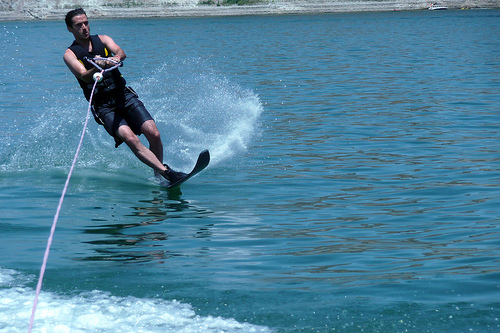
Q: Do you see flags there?
A: No, there are no flags.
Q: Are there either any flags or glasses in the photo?
A: No, there are no flags or glasses.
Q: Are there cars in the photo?
A: No, there are no cars.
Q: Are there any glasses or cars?
A: No, there are no cars or glasses.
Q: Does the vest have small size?
A: Yes, the vest is small.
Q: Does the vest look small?
A: Yes, the vest is small.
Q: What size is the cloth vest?
A: The vest is small.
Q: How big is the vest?
A: The vest is small.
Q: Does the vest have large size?
A: No, the vest is small.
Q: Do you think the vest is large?
A: No, the vest is small.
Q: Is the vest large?
A: No, the vest is small.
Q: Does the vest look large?
A: No, the vest is small.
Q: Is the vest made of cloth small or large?
A: The vest is small.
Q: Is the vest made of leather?
A: No, the vest is made of cloth.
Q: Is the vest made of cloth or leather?
A: The vest is made of cloth.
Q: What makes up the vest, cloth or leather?
A: The vest is made of cloth.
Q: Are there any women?
A: No, there are no women.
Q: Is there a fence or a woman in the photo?
A: No, there are no women or fences.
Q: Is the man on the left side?
A: Yes, the man is on the left of the image.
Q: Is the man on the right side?
A: No, the man is on the left of the image.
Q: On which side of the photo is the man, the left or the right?
A: The man is on the left of the image.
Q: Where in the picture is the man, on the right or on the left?
A: The man is on the left of the image.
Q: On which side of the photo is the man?
A: The man is on the left of the image.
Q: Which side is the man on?
A: The man is on the left of the image.